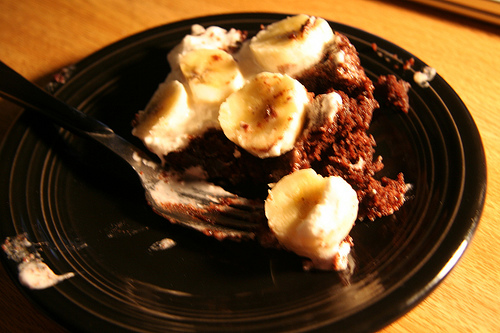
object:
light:
[331, 267, 388, 313]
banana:
[258, 176, 369, 253]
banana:
[220, 75, 317, 162]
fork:
[1, 61, 276, 244]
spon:
[0, 57, 274, 247]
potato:
[216, 70, 309, 159]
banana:
[130, 72, 217, 167]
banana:
[165, 23, 248, 87]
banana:
[233, 13, 335, 82]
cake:
[288, 31, 416, 223]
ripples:
[0, 9, 491, 332]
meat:
[296, 40, 415, 221]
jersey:
[199, 8, 376, 178]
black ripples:
[185, 298, 262, 326]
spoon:
[0, 59, 278, 247]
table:
[0, 0, 499, 333]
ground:
[440, 40, 488, 65]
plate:
[2, 11, 487, 332]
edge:
[443, 82, 485, 234]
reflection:
[323, 268, 387, 318]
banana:
[217, 70, 309, 159]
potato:
[264, 168, 366, 275]